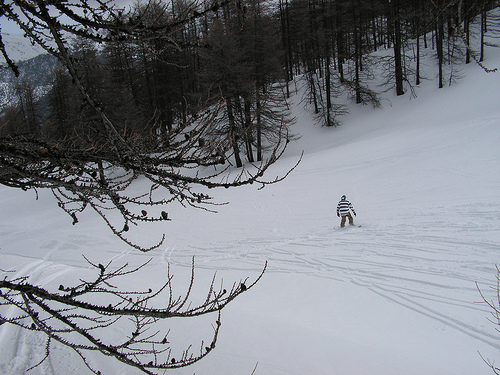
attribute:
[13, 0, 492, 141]
hill — one, snow-covered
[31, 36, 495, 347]
snow — some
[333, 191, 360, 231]
man — one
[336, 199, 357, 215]
sweater — one, striped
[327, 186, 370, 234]
man — one, skiing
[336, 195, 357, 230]
man — one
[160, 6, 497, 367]
hill — one, snow-covered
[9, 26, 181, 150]
mountains — snow-covered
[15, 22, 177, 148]
snow — some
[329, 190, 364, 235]
man — one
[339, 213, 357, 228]
pants — long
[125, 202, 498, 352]
tracks — snow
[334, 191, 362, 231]
person — one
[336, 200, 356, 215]
shirt — striped, one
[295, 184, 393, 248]
man — one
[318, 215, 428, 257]
snowboard — one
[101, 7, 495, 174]
trees — bare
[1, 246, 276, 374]
branch — one, bare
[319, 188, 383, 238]
person — one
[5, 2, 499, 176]
trees — many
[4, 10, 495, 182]
hill — one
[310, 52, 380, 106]
trees — bare, some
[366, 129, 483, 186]
snow — some